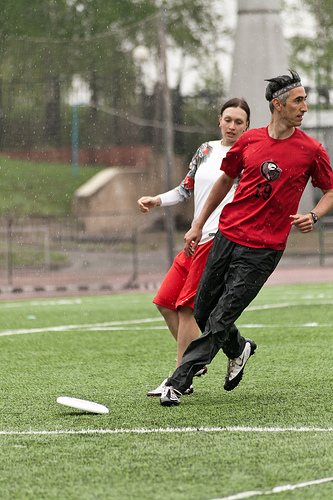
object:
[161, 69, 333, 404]
man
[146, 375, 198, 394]
cleat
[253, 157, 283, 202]
logo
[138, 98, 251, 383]
woman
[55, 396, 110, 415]
frisbee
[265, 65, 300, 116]
hair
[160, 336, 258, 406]
shoe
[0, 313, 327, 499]
line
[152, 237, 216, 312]
shorts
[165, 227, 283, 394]
pant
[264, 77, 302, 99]
band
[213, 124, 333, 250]
shirt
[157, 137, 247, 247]
shirt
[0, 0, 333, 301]
rain drops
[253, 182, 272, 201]
number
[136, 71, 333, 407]
people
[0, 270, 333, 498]
in  a field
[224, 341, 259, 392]
cleat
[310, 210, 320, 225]
watch